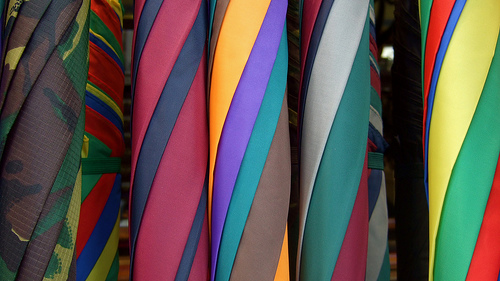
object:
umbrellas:
[0, 0, 498, 279]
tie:
[0, 0, 93, 280]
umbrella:
[416, 0, 499, 280]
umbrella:
[294, 0, 371, 279]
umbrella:
[203, 0, 290, 280]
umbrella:
[129, 0, 206, 279]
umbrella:
[69, 0, 126, 279]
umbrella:
[0, 0, 92, 278]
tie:
[414, 1, 499, 279]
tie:
[293, 0, 400, 279]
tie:
[204, 0, 297, 279]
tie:
[129, 0, 217, 279]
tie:
[72, 0, 127, 279]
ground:
[377, 100, 407, 120]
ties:
[1, 0, 499, 280]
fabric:
[0, 0, 499, 275]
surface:
[374, 0, 424, 280]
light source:
[378, 45, 396, 70]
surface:
[57, 0, 119, 280]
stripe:
[412, 0, 499, 273]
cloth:
[61, 0, 144, 279]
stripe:
[463, 154, 500, 280]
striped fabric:
[208, 0, 292, 279]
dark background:
[376, 0, 430, 280]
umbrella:
[198, 0, 293, 279]